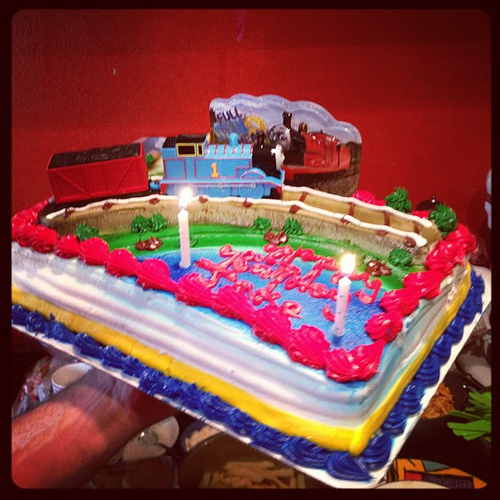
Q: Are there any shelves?
A: No, there are no shelves.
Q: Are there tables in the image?
A: Yes, there is a table.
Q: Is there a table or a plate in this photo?
A: Yes, there is a table.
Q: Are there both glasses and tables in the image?
A: No, there is a table but no glasses.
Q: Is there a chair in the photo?
A: No, there are no chairs.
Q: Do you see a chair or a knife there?
A: No, there are no chairs or knives.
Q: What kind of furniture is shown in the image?
A: The furniture is a table.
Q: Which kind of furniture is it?
A: The piece of furniture is a table.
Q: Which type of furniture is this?
A: This is a table.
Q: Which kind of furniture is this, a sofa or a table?
A: This is a table.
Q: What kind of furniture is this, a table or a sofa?
A: This is a table.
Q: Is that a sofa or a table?
A: That is a table.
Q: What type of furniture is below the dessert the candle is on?
A: The piece of furniture is a table.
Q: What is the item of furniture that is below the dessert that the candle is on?
A: The piece of furniture is a table.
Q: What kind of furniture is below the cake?
A: The piece of furniture is a table.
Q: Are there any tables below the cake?
A: Yes, there is a table below the cake.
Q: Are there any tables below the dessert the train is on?
A: Yes, there is a table below the cake.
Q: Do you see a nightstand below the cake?
A: No, there is a table below the cake.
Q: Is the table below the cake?
A: Yes, the table is below the cake.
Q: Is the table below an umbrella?
A: No, the table is below the cake.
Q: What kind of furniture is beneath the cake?
A: The piece of furniture is a table.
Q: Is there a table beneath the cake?
A: Yes, there is a table beneath the cake.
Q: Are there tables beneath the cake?
A: Yes, there is a table beneath the cake.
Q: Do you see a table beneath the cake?
A: Yes, there is a table beneath the cake.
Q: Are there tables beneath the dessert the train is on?
A: Yes, there is a table beneath the cake.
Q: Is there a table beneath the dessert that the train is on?
A: Yes, there is a table beneath the cake.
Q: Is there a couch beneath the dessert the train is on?
A: No, there is a table beneath the cake.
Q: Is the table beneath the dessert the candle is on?
A: Yes, the table is beneath the cake.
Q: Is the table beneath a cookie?
A: No, the table is beneath the cake.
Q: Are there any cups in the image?
A: Yes, there is a cup.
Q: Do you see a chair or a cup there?
A: Yes, there is a cup.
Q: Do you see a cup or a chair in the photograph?
A: Yes, there is a cup.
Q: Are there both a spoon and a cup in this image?
A: Yes, there are both a cup and a spoon.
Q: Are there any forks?
A: No, there are no forks.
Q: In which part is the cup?
A: The cup is on the left of the image.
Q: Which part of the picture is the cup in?
A: The cup is on the left of the image.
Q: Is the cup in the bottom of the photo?
A: Yes, the cup is in the bottom of the image.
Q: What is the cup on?
A: The cup is on the table.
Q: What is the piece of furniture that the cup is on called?
A: The piece of furniture is a table.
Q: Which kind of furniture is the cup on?
A: The cup is on the table.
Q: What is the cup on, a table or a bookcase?
A: The cup is on a table.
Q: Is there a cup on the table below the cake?
A: Yes, there is a cup on the table.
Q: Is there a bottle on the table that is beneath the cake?
A: No, there is a cup on the table.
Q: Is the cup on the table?
A: Yes, the cup is on the table.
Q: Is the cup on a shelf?
A: No, the cup is on the table.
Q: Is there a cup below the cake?
A: Yes, there is a cup below the cake.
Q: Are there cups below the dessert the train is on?
A: Yes, there is a cup below the cake.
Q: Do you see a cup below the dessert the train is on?
A: Yes, there is a cup below the cake.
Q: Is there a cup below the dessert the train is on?
A: Yes, there is a cup below the cake.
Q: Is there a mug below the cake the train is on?
A: No, there is a cup below the cake.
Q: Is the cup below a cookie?
A: No, the cup is below a cake.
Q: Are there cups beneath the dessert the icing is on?
A: Yes, there is a cup beneath the cake.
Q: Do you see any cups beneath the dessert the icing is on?
A: Yes, there is a cup beneath the cake.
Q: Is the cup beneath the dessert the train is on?
A: Yes, the cup is beneath the cake.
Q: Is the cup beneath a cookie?
A: No, the cup is beneath the cake.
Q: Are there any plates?
A: Yes, there is a plate.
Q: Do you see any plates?
A: Yes, there is a plate.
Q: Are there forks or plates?
A: Yes, there is a plate.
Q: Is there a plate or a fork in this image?
A: Yes, there is a plate.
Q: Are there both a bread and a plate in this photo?
A: No, there is a plate but no breads.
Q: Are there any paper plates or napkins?
A: Yes, there is a paper plate.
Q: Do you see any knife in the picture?
A: No, there are no knives.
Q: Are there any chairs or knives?
A: No, there are no knives or chairs.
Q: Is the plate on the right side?
A: Yes, the plate is on the right of the image.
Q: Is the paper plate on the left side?
A: No, the plate is on the right of the image.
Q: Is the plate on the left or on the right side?
A: The plate is on the right of the image.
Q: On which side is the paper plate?
A: The plate is on the right of the image.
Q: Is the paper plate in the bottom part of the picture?
A: Yes, the plate is in the bottom of the image.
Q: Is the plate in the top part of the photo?
A: No, the plate is in the bottom of the image.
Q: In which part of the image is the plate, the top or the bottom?
A: The plate is in the bottom of the image.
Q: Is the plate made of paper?
A: Yes, the plate is made of paper.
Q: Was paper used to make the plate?
A: Yes, the plate is made of paper.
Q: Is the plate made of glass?
A: No, the plate is made of paper.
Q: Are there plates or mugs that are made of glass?
A: No, there is a plate but it is made of paper.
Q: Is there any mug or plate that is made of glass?
A: No, there is a plate but it is made of paper.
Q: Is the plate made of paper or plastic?
A: The plate is made of paper.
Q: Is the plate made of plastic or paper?
A: The plate is made of paper.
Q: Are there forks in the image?
A: No, there are no forks.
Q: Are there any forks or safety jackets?
A: No, there are no forks or safety jackets.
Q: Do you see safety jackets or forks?
A: No, there are no forks or safety jackets.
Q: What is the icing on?
A: The icing is on the cake.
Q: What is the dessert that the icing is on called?
A: The dessert is a cake.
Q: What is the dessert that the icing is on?
A: The dessert is a cake.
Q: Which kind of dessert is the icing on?
A: The icing is on the cake.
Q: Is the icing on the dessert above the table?
A: Yes, the icing is on the cake.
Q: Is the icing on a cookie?
A: No, the icing is on the cake.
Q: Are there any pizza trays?
A: No, there are no pizza trays.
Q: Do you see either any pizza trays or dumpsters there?
A: No, there are no pizza trays or dumpsters.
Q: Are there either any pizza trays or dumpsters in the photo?
A: No, there are no pizza trays or dumpsters.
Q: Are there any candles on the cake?
A: Yes, there is a candle on the cake.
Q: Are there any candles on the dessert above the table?
A: Yes, there is a candle on the cake.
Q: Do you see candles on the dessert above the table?
A: Yes, there is a candle on the cake.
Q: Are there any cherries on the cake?
A: No, there is a candle on the cake.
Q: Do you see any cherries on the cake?
A: No, there is a candle on the cake.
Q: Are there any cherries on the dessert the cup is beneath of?
A: No, there is a candle on the cake.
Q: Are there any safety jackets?
A: No, there are no safety jackets.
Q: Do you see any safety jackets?
A: No, there are no safety jackets.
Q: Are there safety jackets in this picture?
A: No, there are no safety jackets.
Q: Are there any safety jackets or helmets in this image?
A: No, there are no safety jackets or helmets.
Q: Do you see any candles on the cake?
A: Yes, there is a candle on the cake.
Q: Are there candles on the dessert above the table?
A: Yes, there is a candle on the cake.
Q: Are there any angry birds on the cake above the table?
A: No, there is a candle on the cake.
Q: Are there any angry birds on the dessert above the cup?
A: No, there is a candle on the cake.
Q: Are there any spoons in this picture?
A: Yes, there is a spoon.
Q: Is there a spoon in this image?
A: Yes, there is a spoon.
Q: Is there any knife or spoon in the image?
A: Yes, there is a spoon.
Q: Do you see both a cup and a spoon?
A: Yes, there are both a spoon and a cup.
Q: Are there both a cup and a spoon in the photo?
A: Yes, there are both a spoon and a cup.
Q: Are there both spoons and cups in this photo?
A: Yes, there are both a spoon and a cup.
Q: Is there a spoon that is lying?
A: Yes, there is a spoon that is lying.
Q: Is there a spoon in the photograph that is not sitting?
A: Yes, there is a spoon that is lying.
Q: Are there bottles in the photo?
A: No, there are no bottles.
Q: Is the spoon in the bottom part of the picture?
A: Yes, the spoon is in the bottom of the image.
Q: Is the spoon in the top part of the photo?
A: No, the spoon is in the bottom of the image.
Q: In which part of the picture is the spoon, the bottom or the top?
A: The spoon is in the bottom of the image.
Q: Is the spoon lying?
A: Yes, the spoon is lying.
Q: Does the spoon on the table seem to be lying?
A: Yes, the spoon is lying.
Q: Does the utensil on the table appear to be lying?
A: Yes, the spoon is lying.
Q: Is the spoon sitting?
A: No, the spoon is lying.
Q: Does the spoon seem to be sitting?
A: No, the spoon is lying.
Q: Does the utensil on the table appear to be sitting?
A: No, the spoon is lying.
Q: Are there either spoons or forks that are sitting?
A: No, there is a spoon but it is lying.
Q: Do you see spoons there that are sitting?
A: No, there is a spoon but it is lying.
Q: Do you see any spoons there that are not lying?
A: No, there is a spoon but it is lying.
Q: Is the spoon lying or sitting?
A: The spoon is lying.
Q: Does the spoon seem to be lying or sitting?
A: The spoon is lying.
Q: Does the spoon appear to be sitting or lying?
A: The spoon is lying.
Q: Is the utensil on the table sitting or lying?
A: The spoon is lying.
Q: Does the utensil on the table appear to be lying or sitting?
A: The spoon is lying.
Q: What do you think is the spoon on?
A: The spoon is on the table.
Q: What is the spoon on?
A: The spoon is on the table.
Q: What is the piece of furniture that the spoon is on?
A: The piece of furniture is a table.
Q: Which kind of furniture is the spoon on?
A: The spoon is on the table.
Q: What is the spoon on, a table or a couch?
A: The spoon is on a table.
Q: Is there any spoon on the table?
A: Yes, there is a spoon on the table.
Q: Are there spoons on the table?
A: Yes, there is a spoon on the table.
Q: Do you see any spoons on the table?
A: Yes, there is a spoon on the table.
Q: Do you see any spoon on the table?
A: Yes, there is a spoon on the table.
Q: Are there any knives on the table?
A: No, there is a spoon on the table.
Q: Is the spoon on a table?
A: Yes, the spoon is on a table.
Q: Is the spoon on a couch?
A: No, the spoon is on a table.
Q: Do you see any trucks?
A: No, there are no trucks.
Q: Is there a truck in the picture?
A: No, there are no trucks.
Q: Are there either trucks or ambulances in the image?
A: No, there are no trucks or ambulances.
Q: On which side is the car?
A: The car is on the left of the image.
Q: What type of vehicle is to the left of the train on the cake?
A: The vehicle is a car.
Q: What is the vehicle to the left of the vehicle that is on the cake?
A: The vehicle is a car.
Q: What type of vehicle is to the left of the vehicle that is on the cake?
A: The vehicle is a car.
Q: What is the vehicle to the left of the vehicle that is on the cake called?
A: The vehicle is a car.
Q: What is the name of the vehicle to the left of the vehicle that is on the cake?
A: The vehicle is a car.